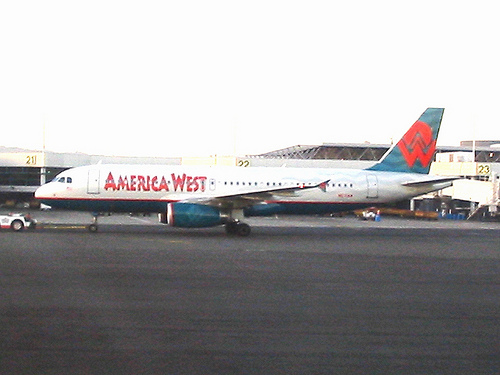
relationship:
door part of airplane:
[86, 166, 103, 194] [34, 106, 466, 239]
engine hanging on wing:
[167, 202, 229, 227] [179, 176, 332, 236]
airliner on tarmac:
[34, 107, 467, 236] [8, 221, 484, 362]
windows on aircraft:
[98, 176, 356, 191] [31, 105, 476, 237]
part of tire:
[172, 198, 186, 221] [236, 222, 252, 237]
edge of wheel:
[238, 218, 255, 226] [220, 219, 251, 241]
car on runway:
[4, 205, 46, 242] [29, 205, 358, 353]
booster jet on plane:
[161, 197, 230, 231] [19, 115, 464, 217]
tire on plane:
[236, 220, 253, 240] [33, 108, 468, 238]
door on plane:
[86, 168, 101, 195] [33, 108, 468, 238]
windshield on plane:
[52, 176, 64, 181] [33, 108, 468, 238]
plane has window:
[33, 108, 468, 238] [346, 182, 355, 188]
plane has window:
[33, 108, 468, 238] [342, 182, 347, 188]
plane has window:
[33, 108, 468, 238] [334, 179, 343, 189]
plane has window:
[33, 108, 468, 238] [329, 182, 336, 188]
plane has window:
[33, 108, 468, 238] [277, 181, 284, 188]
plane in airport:
[33, 108, 468, 238] [3, 135, 495, 222]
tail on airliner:
[370, 105, 445, 180] [34, 107, 467, 236]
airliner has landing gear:
[36, 107, 462, 236] [88, 211, 100, 235]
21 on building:
[25, 155, 37, 164] [9, 155, 40, 215]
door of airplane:
[86, 168, 101, 195] [34, 106, 466, 239]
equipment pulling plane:
[84, 212, 256, 240] [1, 202, 117, 249]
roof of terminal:
[237, 137, 499, 167] [4, 136, 496, 231]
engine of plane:
[167, 202, 229, 227] [33, 108, 468, 238]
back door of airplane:
[360, 169, 384, 204] [34, 106, 466, 239]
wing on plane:
[177, 177, 342, 207] [27, 100, 469, 231]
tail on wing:
[363, 105, 444, 175] [402, 170, 472, 188]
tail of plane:
[363, 105, 444, 175] [30, 136, 492, 193]